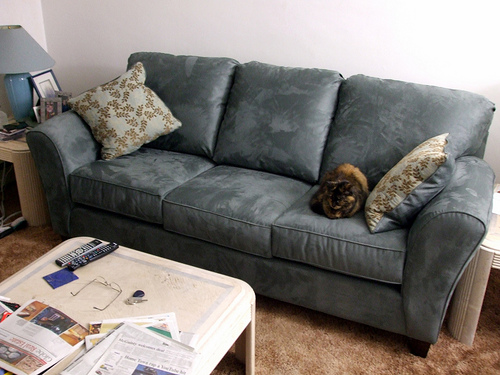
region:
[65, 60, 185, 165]
Decorative two pattern throw pillow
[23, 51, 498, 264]
Blue gray couch with matching pillows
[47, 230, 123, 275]
Television remote controls on table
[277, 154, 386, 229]
Family cat sitting on sofa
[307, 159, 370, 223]
Tortoiseshell colored house cat.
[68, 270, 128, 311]
Prescription eyeglasses resting on living room table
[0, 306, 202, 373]
Newspaper spred out on table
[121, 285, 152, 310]
Set of keys on table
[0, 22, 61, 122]
Blue end table lamp with light blue lampshade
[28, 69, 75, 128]
Several pictures sitting on end table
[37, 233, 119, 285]
two remotes sitting on the table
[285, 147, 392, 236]
an orange and black cat sitting on the couch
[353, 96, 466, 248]
blue and white pillow on the couch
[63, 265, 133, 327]
pair of eye glasses on the table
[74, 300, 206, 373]
newspapers on the table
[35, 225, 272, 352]
white coffee table in the living room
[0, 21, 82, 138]
blue and gray lamp on the end table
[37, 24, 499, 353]
blue couch in the living room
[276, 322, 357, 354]
brown carpet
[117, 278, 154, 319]
keys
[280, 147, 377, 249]
cat sleeping on the couch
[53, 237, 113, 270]
remote controls on the table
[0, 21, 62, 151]
lamp sitting in the corner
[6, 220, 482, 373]
brown carpet all across the floor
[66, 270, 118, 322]
a pair of glasses on the table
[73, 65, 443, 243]
flowery cushions on the couch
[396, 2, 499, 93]
light reflection on the wall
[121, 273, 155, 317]
keys sitting on the table top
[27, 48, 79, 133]
pictures and flower next to the lamp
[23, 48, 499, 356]
A LIVING ROOM SOFA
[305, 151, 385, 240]
A CAT SITTING ON A SOFA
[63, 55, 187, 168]
A THROW PILLOW ON A SOFA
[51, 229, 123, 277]
TWO REMOTE CONTROLS ON THE COFFEE TABLE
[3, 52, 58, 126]
A BLUE LAMP ON A SIDE TABLE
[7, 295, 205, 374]
PAPERS ON A COFFEE TABLE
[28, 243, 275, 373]
A WHITE COFFEE TABLE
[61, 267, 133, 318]
A PAIR OF GLASSES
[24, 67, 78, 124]
PICTURES ON A SIDE TABLE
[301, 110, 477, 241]
A CAT SITTING NEXT TO A THROW PILLOW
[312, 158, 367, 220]
A brown dog sleepimg on a coach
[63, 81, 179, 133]
A cushion pillow on a coach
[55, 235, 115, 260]
Two slim remote control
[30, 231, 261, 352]
A small plastic table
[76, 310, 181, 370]
Separated newspapers on a table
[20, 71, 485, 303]
A three sitter grey coach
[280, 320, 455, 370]
A brown woolen carpet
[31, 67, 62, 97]
A wooden empty photo frame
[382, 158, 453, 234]
A cushion pillow on a coach